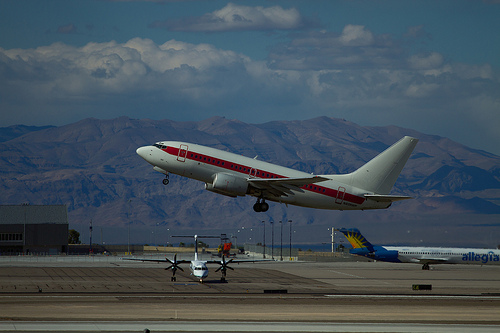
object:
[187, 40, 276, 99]
clouds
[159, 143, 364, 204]
stripe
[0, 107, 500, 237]
hill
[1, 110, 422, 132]
montian tops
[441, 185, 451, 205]
ground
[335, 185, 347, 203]
door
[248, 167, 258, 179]
door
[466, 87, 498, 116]
ground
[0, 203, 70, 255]
building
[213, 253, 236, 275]
propeller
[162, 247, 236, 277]
two propellors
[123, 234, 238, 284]
airplane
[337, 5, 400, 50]
clouds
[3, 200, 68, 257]
hanger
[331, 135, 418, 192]
white tail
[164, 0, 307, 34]
cloud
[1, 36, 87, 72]
cloud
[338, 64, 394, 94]
cloud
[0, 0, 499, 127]
sky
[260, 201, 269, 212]
tires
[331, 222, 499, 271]
airplane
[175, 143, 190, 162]
door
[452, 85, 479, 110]
clouds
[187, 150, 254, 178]
windows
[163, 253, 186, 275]
propeller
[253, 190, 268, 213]
landing gear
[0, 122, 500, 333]
airport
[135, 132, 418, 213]
airplane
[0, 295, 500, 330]
runway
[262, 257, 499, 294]
tarmac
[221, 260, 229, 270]
engine